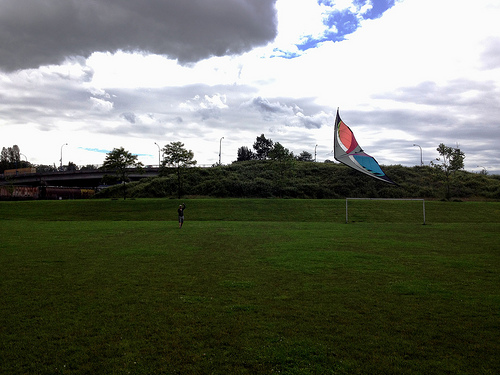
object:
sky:
[0, 1, 500, 159]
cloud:
[1, 0, 278, 71]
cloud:
[383, 74, 500, 106]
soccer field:
[0, 217, 498, 374]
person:
[176, 202, 187, 228]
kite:
[333, 108, 403, 188]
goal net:
[344, 196, 427, 224]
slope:
[0, 192, 500, 221]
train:
[0, 182, 99, 199]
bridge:
[1, 172, 163, 184]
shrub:
[281, 185, 306, 199]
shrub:
[208, 178, 230, 198]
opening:
[283, 1, 395, 62]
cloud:
[186, 95, 228, 120]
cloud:
[87, 98, 114, 119]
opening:
[90, 148, 145, 159]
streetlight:
[58, 142, 67, 170]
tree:
[436, 140, 463, 198]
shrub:
[377, 185, 410, 197]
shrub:
[408, 185, 439, 197]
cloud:
[353, 107, 500, 140]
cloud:
[467, 35, 498, 71]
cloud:
[290, 114, 323, 128]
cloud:
[256, 97, 288, 118]